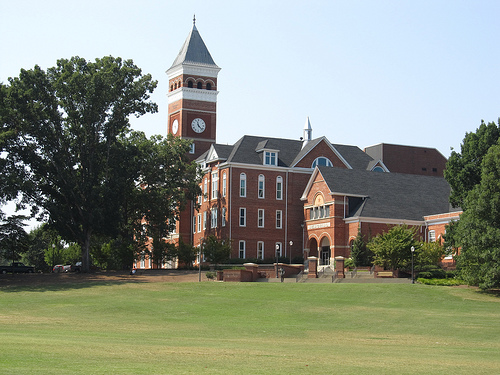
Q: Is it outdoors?
A: Yes, it is outdoors.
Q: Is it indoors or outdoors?
A: It is outdoors.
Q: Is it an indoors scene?
A: No, it is outdoors.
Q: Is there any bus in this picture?
A: No, there are no buses.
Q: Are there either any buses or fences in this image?
A: No, there are no buses or fences.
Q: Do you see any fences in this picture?
A: No, there are no fences.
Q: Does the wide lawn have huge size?
A: Yes, the lawn is huge.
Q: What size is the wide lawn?
A: The lawn is huge.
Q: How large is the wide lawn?
A: The lawn is huge.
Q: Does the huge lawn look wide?
A: Yes, the lawn is wide.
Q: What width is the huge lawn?
A: The lawn is wide.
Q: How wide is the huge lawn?
A: The lawn is wide.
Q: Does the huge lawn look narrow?
A: No, the lawn is wide.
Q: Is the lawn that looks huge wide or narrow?
A: The lawn is wide.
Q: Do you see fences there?
A: No, there are no fences.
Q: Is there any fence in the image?
A: No, there are no fences.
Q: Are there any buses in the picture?
A: No, there are no buses.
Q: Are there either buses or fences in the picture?
A: No, there are no buses or fences.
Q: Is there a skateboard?
A: No, there are no skateboards.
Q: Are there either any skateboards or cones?
A: No, there are no skateboards or cones.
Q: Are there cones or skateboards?
A: No, there are no skateboards or cones.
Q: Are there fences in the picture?
A: No, there are no fences.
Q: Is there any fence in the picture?
A: No, there are no fences.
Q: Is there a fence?
A: No, there are no fences.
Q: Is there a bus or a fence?
A: No, there are no fences or buses.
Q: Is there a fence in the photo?
A: No, there are no fences.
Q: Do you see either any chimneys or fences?
A: No, there are no fences or chimneys.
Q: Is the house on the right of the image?
A: Yes, the house is on the right of the image.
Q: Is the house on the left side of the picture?
A: No, the house is on the right of the image.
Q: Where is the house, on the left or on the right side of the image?
A: The house is on the right of the image.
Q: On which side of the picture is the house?
A: The house is on the right of the image.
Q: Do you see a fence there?
A: No, there are no fences.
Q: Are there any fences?
A: No, there are no fences.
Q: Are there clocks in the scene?
A: Yes, there is a clock.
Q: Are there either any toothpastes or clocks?
A: Yes, there is a clock.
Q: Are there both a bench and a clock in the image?
A: No, there is a clock but no benches.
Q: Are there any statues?
A: No, there are no statues.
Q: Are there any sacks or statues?
A: No, there are no statues or sacks.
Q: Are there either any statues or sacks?
A: No, there are no statues or sacks.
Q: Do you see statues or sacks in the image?
A: No, there are no statues or sacks.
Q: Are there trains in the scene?
A: No, there are no trains.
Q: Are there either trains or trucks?
A: No, there are no trains or trucks.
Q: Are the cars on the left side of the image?
A: Yes, the cars are on the left of the image.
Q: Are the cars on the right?
A: No, the cars are on the left of the image.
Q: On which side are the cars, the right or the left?
A: The cars are on the left of the image.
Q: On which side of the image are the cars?
A: The cars are on the left of the image.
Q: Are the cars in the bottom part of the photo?
A: Yes, the cars are in the bottom of the image.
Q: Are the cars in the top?
A: No, the cars are in the bottom of the image.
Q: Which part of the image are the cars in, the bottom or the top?
A: The cars are in the bottom of the image.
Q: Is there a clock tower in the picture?
A: Yes, there is a clock tower.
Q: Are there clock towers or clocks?
A: Yes, there is a clock tower.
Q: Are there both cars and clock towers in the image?
A: Yes, there are both a clock tower and a car.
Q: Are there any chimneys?
A: No, there are no chimneys.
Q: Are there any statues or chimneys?
A: No, there are no chimneys or statues.